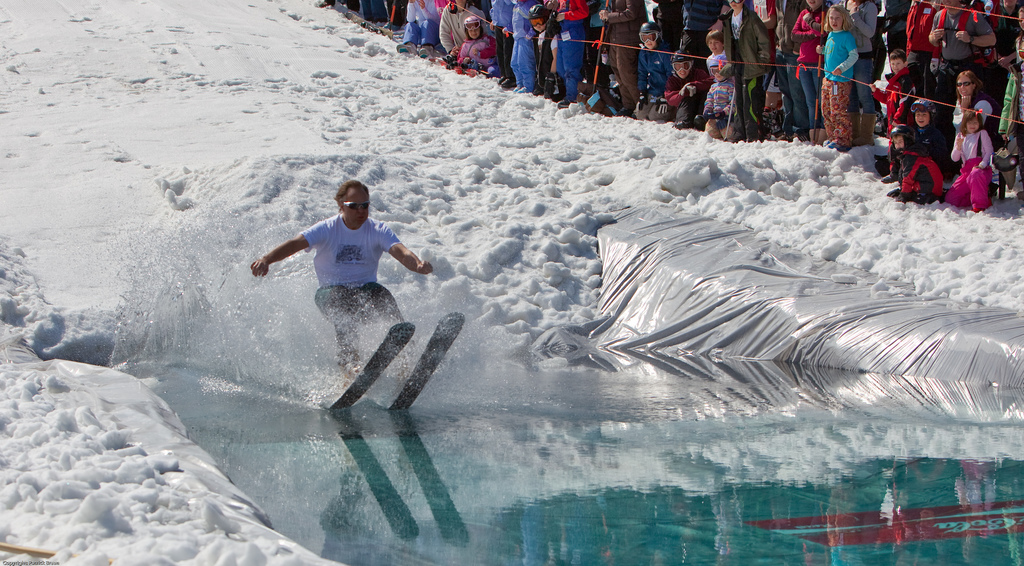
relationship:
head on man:
[329, 175, 390, 233] [250, 180, 464, 406]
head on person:
[957, 106, 986, 141] [957, 106, 986, 141]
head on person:
[907, 96, 927, 129] [907, 96, 927, 129]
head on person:
[948, 70, 983, 94] [948, 70, 983, 94]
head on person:
[698, 51, 744, 87] [679, 3, 744, 87]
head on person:
[661, 34, 701, 96] [661, 34, 701, 96]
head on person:
[609, 20, 714, 109] [609, 20, 714, 109]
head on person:
[448, 10, 494, 33] [448, 10, 494, 33]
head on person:
[512, 0, 573, 40] [512, 0, 573, 40]